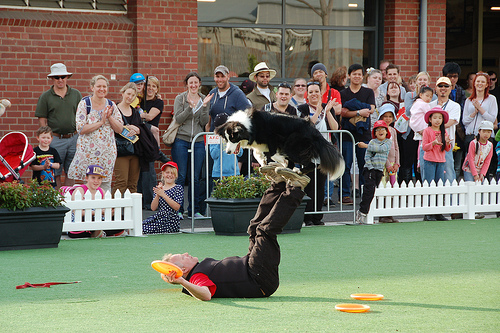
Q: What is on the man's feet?
A: A dog.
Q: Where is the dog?
A: On the man's feet.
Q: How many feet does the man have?
A: 2.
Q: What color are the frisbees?
A: Orange.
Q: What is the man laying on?
A: His back.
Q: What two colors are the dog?
A: Black and white.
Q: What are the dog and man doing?
A: Performing stunts.